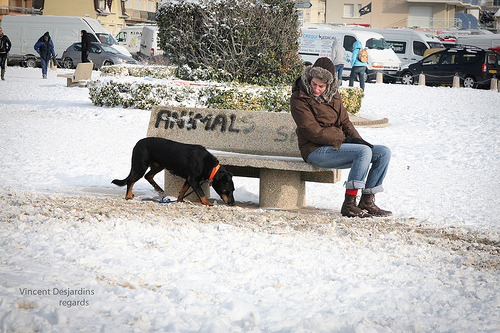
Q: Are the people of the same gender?
A: No, they are both male and female.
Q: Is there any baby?
A: No, there are no babies.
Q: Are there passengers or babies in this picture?
A: No, there are no babies or passengers.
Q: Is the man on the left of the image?
A: Yes, the man is on the left of the image.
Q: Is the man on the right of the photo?
A: No, the man is on the left of the image.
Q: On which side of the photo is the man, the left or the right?
A: The man is on the left of the image.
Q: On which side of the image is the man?
A: The man is on the left of the image.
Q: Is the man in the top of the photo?
A: Yes, the man is in the top of the image.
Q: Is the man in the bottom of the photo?
A: No, the man is in the top of the image.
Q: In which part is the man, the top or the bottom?
A: The man is in the top of the image.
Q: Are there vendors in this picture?
A: No, there are no vendors.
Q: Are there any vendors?
A: No, there are no vendors.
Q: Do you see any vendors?
A: No, there are no vendors.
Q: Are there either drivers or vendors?
A: No, there are no vendors or drivers.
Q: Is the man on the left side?
A: Yes, the man is on the left of the image.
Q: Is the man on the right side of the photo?
A: No, the man is on the left of the image.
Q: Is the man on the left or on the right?
A: The man is on the left of the image.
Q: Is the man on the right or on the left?
A: The man is on the left of the image.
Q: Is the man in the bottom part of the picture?
A: No, the man is in the top of the image.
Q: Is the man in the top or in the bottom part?
A: The man is in the top of the image.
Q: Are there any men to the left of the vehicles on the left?
A: Yes, there is a man to the left of the vehicles.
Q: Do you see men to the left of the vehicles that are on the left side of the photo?
A: Yes, there is a man to the left of the vehicles.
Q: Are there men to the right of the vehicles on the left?
A: No, the man is to the left of the vehicles.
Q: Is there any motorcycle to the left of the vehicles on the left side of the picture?
A: No, there is a man to the left of the vehicles.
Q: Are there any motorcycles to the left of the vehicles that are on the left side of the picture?
A: No, there is a man to the left of the vehicles.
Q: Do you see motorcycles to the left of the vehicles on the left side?
A: No, there is a man to the left of the vehicles.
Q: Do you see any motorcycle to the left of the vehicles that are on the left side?
A: No, there is a man to the left of the vehicles.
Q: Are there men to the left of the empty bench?
A: Yes, there is a man to the left of the bench.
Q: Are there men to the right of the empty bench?
A: No, the man is to the left of the bench.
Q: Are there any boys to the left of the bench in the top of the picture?
A: No, there is a man to the left of the bench.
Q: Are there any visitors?
A: No, there are no visitors.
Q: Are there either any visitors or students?
A: No, there are no visitors or students.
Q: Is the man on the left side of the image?
A: Yes, the man is on the left of the image.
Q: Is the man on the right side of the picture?
A: No, the man is on the left of the image.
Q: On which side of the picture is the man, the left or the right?
A: The man is on the left of the image.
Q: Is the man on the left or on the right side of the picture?
A: The man is on the left of the image.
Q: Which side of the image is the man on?
A: The man is on the left of the image.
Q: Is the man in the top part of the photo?
A: Yes, the man is in the top of the image.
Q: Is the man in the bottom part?
A: No, the man is in the top of the image.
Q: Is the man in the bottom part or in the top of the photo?
A: The man is in the top of the image.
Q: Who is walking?
A: The man is walking.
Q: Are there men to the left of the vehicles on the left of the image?
A: Yes, there is a man to the left of the vehicles.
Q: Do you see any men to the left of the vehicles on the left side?
A: Yes, there is a man to the left of the vehicles.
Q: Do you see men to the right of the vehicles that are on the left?
A: No, the man is to the left of the vehicles.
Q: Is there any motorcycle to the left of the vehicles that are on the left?
A: No, there is a man to the left of the vehicles.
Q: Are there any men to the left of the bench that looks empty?
A: Yes, there is a man to the left of the bench.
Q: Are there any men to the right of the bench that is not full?
A: No, the man is to the left of the bench.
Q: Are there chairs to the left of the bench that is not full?
A: No, there is a man to the left of the bench.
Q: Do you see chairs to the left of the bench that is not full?
A: No, there is a man to the left of the bench.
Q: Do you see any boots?
A: Yes, there are boots.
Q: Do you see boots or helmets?
A: Yes, there are boots.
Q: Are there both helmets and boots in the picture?
A: No, there are boots but no helmets.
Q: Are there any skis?
A: No, there are no skis.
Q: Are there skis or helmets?
A: No, there are no skis or helmets.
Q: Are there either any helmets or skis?
A: No, there are no skis or helmets.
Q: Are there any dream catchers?
A: No, there are no dream catchers.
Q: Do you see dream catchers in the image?
A: No, there are no dream catchers.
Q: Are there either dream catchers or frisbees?
A: No, there are no dream catchers or frisbees.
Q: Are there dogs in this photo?
A: Yes, there is a dog.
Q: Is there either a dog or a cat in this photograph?
A: Yes, there is a dog.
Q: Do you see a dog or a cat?
A: Yes, there is a dog.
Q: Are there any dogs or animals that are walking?
A: Yes, the dog is walking.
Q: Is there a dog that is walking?
A: Yes, there is a dog that is walking.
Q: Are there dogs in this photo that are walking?
A: Yes, there is a dog that is walking.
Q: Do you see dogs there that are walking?
A: Yes, there is a dog that is walking.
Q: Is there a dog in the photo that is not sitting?
A: Yes, there is a dog that is walking.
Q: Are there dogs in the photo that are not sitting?
A: Yes, there is a dog that is walking.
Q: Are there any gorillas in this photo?
A: No, there are no gorillas.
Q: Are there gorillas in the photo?
A: No, there are no gorillas.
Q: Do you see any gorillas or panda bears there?
A: No, there are no gorillas or panda bears.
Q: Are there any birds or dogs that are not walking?
A: No, there is a dog but it is walking.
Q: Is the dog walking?
A: Yes, the dog is walking.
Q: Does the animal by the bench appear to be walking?
A: Yes, the dog is walking.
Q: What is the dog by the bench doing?
A: The dog is walking.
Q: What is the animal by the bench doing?
A: The dog is walking.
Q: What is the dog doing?
A: The dog is walking.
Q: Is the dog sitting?
A: No, the dog is walking.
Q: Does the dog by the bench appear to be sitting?
A: No, the dog is walking.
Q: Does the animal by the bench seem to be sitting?
A: No, the dog is walking.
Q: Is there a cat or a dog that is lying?
A: No, there is a dog but it is walking.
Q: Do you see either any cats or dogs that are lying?
A: No, there is a dog but it is walking.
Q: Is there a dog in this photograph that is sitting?
A: No, there is a dog but it is walking.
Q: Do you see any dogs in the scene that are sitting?
A: No, there is a dog but it is walking.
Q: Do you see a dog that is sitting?
A: No, there is a dog but it is walking.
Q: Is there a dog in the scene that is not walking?
A: No, there is a dog but it is walking.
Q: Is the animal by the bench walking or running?
A: The dog is walking.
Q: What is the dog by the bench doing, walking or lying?
A: The dog is walking.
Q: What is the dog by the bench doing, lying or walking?
A: The dog is walking.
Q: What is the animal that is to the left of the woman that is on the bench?
A: The animal is a dog.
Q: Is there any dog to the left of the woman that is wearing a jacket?
A: Yes, there is a dog to the left of the woman.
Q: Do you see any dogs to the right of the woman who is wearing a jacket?
A: No, the dog is to the left of the woman.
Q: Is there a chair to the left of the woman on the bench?
A: No, there is a dog to the left of the woman.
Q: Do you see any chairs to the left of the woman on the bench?
A: No, there is a dog to the left of the woman.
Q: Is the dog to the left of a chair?
A: No, the dog is to the left of a woman.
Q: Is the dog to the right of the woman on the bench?
A: No, the dog is to the left of the woman.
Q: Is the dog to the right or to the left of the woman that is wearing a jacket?
A: The dog is to the left of the woman.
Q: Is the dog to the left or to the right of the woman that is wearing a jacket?
A: The dog is to the left of the woman.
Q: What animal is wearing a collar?
A: The dog is wearing a collar.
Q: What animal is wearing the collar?
A: The dog is wearing a collar.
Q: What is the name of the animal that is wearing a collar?
A: The animal is a dog.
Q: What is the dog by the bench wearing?
A: The dog is wearing a collar.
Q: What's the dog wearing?
A: The dog is wearing a collar.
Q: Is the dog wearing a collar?
A: Yes, the dog is wearing a collar.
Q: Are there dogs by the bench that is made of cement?
A: Yes, there is a dog by the bench.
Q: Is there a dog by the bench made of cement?
A: Yes, there is a dog by the bench.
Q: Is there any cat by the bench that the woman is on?
A: No, there is a dog by the bench.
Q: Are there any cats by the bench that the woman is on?
A: No, there is a dog by the bench.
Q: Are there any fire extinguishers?
A: No, there are no fire extinguishers.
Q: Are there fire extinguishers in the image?
A: No, there are no fire extinguishers.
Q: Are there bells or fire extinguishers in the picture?
A: No, there are no fire extinguishers or bells.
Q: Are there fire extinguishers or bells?
A: No, there are no fire extinguishers or bells.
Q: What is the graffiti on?
A: The graffiti is on the bench.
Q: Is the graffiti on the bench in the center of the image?
A: Yes, the graffiti is on the bench.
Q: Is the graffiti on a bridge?
A: No, the graffiti is on the bench.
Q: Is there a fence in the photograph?
A: No, there are no fences.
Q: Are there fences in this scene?
A: No, there are no fences.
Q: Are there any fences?
A: No, there are no fences.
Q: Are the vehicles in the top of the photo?
A: Yes, the vehicles are in the top of the image.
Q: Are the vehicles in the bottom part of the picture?
A: No, the vehicles are in the top of the image.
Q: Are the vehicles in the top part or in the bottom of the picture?
A: The vehicles are in the top of the image.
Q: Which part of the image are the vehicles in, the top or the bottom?
A: The vehicles are in the top of the image.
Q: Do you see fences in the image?
A: No, there are no fences.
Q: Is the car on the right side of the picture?
A: Yes, the car is on the right of the image.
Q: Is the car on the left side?
A: No, the car is on the right of the image.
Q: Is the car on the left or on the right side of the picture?
A: The car is on the right of the image.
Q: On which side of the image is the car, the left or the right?
A: The car is on the right of the image.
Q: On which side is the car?
A: The car is on the right of the image.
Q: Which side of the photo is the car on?
A: The car is on the right of the image.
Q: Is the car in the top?
A: Yes, the car is in the top of the image.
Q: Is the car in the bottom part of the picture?
A: No, the car is in the top of the image.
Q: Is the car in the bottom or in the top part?
A: The car is in the top of the image.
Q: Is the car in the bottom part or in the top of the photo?
A: The car is in the top of the image.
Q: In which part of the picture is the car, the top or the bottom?
A: The car is in the top of the image.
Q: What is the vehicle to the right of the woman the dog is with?
A: The vehicle is a car.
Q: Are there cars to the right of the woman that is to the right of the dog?
A: Yes, there is a car to the right of the woman.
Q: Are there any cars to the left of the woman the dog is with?
A: No, the car is to the right of the woman.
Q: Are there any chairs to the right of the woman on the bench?
A: No, there is a car to the right of the woman.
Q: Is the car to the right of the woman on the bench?
A: Yes, the car is to the right of the woman.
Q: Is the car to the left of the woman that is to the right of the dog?
A: No, the car is to the right of the woman.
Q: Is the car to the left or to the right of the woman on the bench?
A: The car is to the right of the woman.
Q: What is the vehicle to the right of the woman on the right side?
A: The vehicle is a car.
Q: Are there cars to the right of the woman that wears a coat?
A: Yes, there is a car to the right of the woman.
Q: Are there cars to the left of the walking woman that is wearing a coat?
A: No, the car is to the right of the woman.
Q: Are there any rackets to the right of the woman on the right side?
A: No, there is a car to the right of the woman.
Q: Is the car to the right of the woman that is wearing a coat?
A: Yes, the car is to the right of the woman.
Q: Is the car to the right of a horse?
A: No, the car is to the right of the woman.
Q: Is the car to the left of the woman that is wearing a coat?
A: No, the car is to the right of the woman.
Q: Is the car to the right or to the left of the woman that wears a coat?
A: The car is to the right of the woman.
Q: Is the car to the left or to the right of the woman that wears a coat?
A: The car is to the right of the woman.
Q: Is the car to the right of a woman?
A: Yes, the car is to the right of a woman.